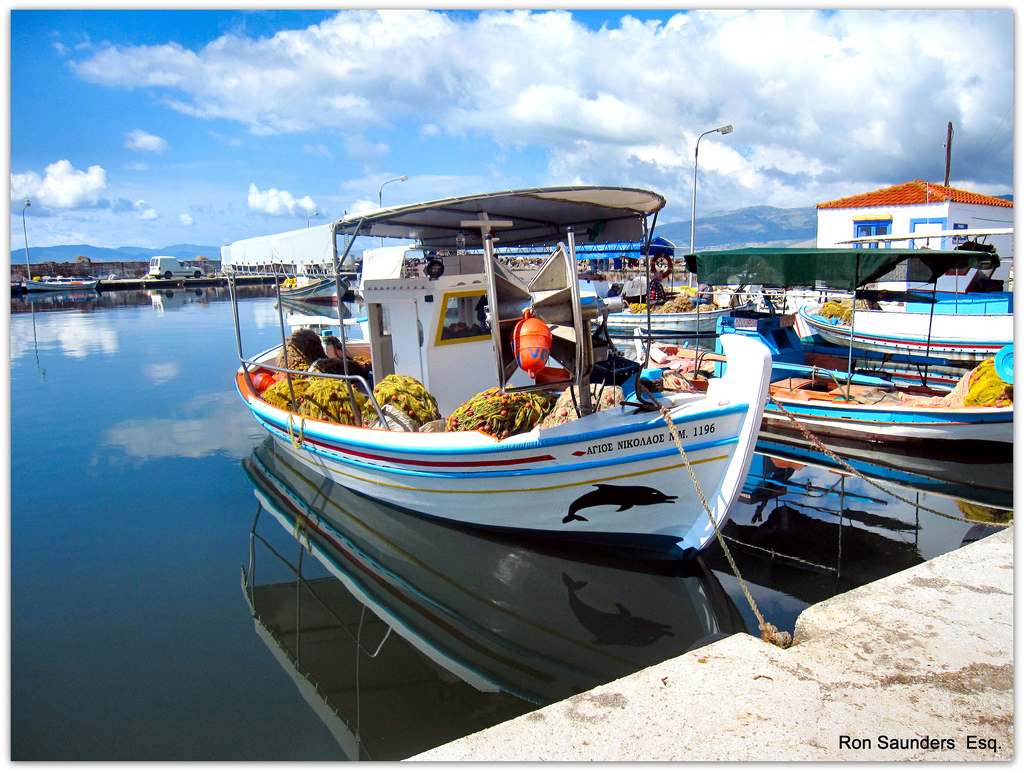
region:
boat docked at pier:
[202, 167, 784, 576]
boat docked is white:
[191, 178, 781, 584]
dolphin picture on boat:
[554, 467, 684, 543]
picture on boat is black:
[545, 473, 683, 537]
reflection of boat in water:
[202, 423, 812, 760]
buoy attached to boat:
[507, 300, 550, 373]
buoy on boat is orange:
[494, 308, 552, 369]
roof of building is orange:
[804, 169, 1010, 215]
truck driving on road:
[137, 248, 202, 286]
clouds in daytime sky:
[12, 10, 1012, 245]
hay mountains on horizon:
[12, 243, 225, 262]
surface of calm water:
[5, 275, 1009, 762]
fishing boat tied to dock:
[218, 183, 1010, 769]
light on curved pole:
[688, 125, 736, 250]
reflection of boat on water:
[237, 439, 747, 762]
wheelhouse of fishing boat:
[363, 277, 506, 420]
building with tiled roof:
[815, 182, 1011, 280]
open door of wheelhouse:
[370, 296, 421, 394]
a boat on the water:
[761, 354, 1009, 449]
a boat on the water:
[602, 264, 733, 334]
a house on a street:
[820, 182, 1002, 260]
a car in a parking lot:
[150, 251, 196, 270]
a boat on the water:
[8, 261, 98, 300]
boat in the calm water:
[229, 177, 765, 557]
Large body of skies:
[43, 47, 256, 175]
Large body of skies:
[343, 31, 555, 139]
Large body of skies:
[111, 54, 241, 214]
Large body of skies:
[122, 59, 282, 186]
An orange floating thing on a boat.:
[498, 297, 559, 384]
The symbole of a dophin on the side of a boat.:
[555, 474, 682, 526]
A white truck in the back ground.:
[138, 247, 206, 282]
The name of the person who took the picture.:
[836, 733, 1007, 757]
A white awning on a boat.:
[211, 179, 665, 282]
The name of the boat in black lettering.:
[580, 418, 730, 463]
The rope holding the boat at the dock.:
[644, 382, 832, 665]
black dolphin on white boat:
[565, 473, 679, 537]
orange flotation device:
[517, 302, 546, 382]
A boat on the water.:
[179, 169, 790, 575]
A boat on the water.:
[680, 348, 1007, 467]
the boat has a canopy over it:
[217, 180, 767, 558]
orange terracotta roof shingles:
[820, 174, 1010, 210]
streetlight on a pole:
[687, 120, 732, 242]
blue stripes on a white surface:
[563, 397, 742, 468]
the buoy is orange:
[513, 315, 549, 382]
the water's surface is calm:
[7, 293, 911, 766]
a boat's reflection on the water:
[209, 433, 681, 741]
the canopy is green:
[702, 247, 985, 295]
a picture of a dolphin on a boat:
[556, 468, 687, 538]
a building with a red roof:
[812, 180, 986, 228]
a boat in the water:
[203, 188, 774, 587]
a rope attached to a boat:
[648, 387, 795, 654]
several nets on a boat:
[278, 342, 433, 423]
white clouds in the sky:
[74, 33, 442, 173]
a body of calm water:
[44, 302, 229, 650]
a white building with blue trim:
[817, 194, 957, 246]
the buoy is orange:
[512, 306, 551, 380]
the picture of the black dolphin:
[560, 480, 677, 523]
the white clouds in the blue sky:
[11, 9, 1020, 265]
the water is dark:
[11, 290, 1011, 762]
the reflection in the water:
[11, 284, 1011, 759]